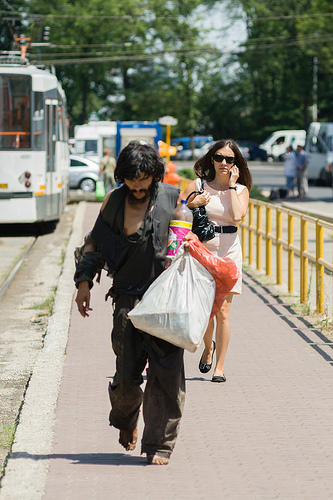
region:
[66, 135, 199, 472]
a homeless man in ragged clothes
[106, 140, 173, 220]
man with dark hair and beard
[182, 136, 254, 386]
well dressed woman on cell phone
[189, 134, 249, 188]
woman with dark hair and sunglasses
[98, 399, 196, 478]
barefoot man walking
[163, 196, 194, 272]
plastic bottle with purple label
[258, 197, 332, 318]
yellow railing by sidewalk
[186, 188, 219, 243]
woman's black purse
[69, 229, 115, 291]
man's torn shirt sleave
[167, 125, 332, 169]
cars on street in background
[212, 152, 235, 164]
Dark pair of sunglasses on woman's face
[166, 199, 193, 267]
Large plastic empty bottle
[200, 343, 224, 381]
Pair of woman's black dress shoes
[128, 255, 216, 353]
White plastic garbage bag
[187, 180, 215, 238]
Woman's black leather purse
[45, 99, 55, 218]
Long metal doors on side of bus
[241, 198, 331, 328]
Long yellow metal poles in ground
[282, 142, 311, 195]
Two men standing in background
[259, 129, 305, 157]
White van in driving down road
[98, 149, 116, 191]
Man walking down sidewalk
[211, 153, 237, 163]
A pair of black sunglasses.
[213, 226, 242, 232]
A black belt.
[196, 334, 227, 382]
A pair of black flats.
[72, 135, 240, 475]
A homeless man walking barefoot.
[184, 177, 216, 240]
A black shoulder bag.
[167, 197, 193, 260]
A clear drink bottle with a purple label.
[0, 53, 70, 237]
A white and grey bus.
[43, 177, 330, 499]
A sidewalk.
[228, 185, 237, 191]
A black wristwatch.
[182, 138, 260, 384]
A woman walking while talking on her cellphone.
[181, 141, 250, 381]
the woman walking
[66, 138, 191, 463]
the man walking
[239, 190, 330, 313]
the yellow poles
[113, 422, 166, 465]
the man's dirty feet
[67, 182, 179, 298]
the man's ripped shirt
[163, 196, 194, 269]
the empty bottle in the man's arms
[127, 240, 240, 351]
the plastic bag the man's carrying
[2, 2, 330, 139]
the green trees in the distance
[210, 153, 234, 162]
the sunglasses on the woman's face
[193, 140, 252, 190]
the hair on the woman's head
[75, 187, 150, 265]
man's shirt is ripped up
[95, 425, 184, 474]
man does not have shoes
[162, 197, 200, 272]
man holding a plastic bottle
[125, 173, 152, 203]
man has a beard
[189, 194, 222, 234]
woman is carrying her purse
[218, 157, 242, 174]
woman is talking on cellphone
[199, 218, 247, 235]
woman has a black belt on her dress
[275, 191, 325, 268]
yellow poles next to the sidewalk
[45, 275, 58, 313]
weeds next to curb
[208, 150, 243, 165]
woman is wearing sunglasses